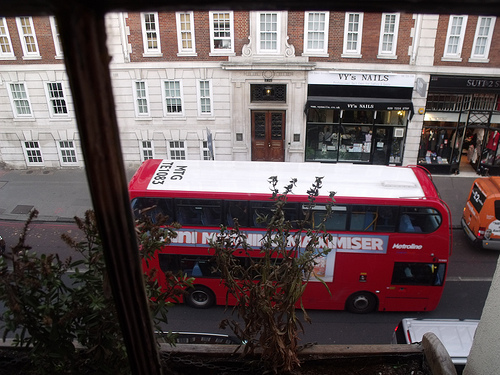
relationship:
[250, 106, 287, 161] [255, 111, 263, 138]
door with windows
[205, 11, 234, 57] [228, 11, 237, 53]
window has trim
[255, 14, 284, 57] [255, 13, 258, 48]
window has trim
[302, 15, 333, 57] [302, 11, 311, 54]
window has trim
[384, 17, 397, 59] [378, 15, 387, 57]
window has trim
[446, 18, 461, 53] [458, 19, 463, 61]
window has trim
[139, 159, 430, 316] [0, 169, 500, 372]
bus on road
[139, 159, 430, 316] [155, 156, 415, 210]
bus has roof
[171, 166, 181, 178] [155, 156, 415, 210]
letters on roof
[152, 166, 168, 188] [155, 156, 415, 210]
numbers on roof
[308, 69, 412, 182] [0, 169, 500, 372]
salon across road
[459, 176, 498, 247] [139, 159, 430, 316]
vehicle in front of bus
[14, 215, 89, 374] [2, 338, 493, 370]
plants on windowsill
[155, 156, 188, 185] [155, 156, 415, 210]
text on top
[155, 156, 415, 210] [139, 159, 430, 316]
top of bus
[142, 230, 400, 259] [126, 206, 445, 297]
sign on side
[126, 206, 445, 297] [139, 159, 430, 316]
side on bus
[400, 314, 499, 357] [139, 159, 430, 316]
vehicle beside bus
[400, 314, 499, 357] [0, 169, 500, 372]
vehicle on road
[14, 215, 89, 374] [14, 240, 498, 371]
plants in foreground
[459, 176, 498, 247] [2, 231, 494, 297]
vehicle on road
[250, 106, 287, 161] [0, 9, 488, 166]
doors of building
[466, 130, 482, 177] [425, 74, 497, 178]
entrance of shop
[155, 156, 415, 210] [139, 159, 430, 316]
top on bus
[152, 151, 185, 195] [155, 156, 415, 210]
mtg te1083 on top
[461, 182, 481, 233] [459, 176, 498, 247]
back of vehicle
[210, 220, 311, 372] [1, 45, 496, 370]
plant outside window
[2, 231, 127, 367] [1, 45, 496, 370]
plant outside window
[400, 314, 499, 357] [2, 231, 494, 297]
vehicle on road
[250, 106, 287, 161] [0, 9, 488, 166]
doors on building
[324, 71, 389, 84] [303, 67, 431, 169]
vy's nails above salon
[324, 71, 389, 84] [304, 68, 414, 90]
vy's nails over white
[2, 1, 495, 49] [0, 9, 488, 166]
windows on building